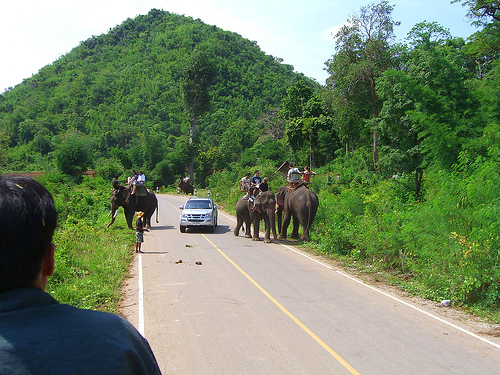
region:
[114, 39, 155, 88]
green leaf on tree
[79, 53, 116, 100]
green leaf on tree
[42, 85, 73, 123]
green leaf on tree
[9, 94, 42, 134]
green leaf on tree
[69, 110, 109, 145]
green leaf on tree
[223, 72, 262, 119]
green leaf on tree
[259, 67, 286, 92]
green leaf on tree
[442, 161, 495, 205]
Green leaves on a tree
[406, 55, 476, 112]
Green leaves on a tree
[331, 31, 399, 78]
Green leaves on a tree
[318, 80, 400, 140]
Green leaves on a tree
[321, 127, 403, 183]
Green leaves on a tree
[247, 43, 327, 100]
Green leaves on a tree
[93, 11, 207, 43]
Green leaves on a tree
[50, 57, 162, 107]
Green leaves on a tree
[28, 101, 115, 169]
Green leaves on a tree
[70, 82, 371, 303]
animals on the road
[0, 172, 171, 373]
a man on the bottom left side of the shot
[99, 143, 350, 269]
the car trying to navigate through the animals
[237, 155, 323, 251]
the elelphants are carryin people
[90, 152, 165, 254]
this elephant is on the side of the road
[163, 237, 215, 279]
elelphant dung on the roadway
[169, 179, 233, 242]
this car is silver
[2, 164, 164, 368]
this man is wearing a blue shirt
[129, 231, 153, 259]
the legs of a man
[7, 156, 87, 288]
the hair of a man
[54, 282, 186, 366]
the shoulder of a man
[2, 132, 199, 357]
a man wearing a shirt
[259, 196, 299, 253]
the trunk of a elephant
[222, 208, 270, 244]
the legs of a elephant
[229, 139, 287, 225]
people on a elephant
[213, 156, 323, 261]
elephants on road's shoulder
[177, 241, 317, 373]
yellow line in road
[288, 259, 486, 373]
white line on shoulder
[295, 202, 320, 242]
elephant has long tail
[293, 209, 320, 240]
elephant has brown tail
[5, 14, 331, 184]
tall green trees in grove behind elephants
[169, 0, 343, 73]
bright clouds in sky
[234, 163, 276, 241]
people sitting on a elephant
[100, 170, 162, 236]
people sitting on a elephant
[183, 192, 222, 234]
jeep on the rode between elephants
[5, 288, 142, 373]
man wearing a blue shirt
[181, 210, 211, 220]
head lights on the jeep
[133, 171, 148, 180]
man wearing a white tee shirt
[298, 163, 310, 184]
woman sitting on a elephant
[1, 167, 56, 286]
man has black hair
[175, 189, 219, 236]
small truck on road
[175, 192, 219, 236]
truck on road is small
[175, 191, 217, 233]
truck on road is silver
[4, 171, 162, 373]
man standing beside road